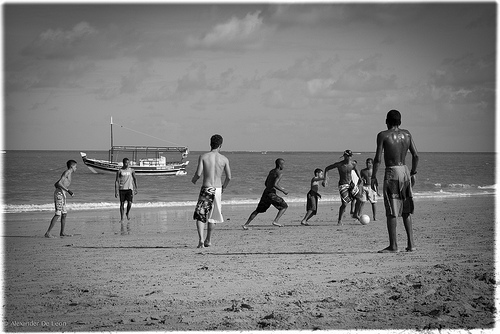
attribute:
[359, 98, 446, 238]
black male — running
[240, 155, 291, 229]
male — black, running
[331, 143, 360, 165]
male — black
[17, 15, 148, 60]
cloud — white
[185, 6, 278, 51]
cloud — white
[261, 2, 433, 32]
cloud — white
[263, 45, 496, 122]
cloud — white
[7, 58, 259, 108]
cloud — white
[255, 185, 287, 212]
shorts — dark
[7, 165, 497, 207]
wave — white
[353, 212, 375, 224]
ball — round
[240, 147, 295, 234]
male — black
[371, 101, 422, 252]
male — dark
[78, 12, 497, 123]
sky — blue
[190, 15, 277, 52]
cloud — white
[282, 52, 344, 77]
cloud — white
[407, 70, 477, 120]
cloud — white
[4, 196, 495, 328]
beach — sandy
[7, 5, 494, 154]
sky — blue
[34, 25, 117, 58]
clouds — white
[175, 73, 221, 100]
clouds — white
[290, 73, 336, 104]
clouds — white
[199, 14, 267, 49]
clouds — white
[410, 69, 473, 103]
clouds — white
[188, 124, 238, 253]
man — playing